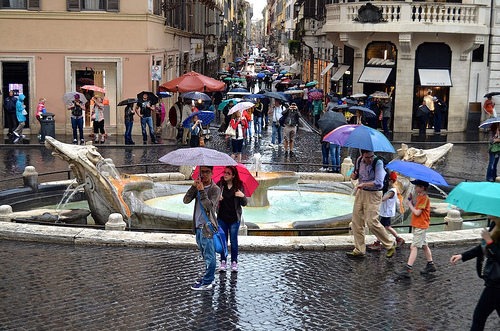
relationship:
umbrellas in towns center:
[4, 68, 499, 216] [1, 79, 497, 322]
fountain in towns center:
[2, 130, 499, 251] [1, 79, 497, 322]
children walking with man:
[319, 121, 449, 293] [322, 121, 401, 265]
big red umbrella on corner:
[155, 67, 229, 99] [1, 2, 214, 138]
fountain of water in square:
[2, 130, 499, 251] [1, 79, 497, 322]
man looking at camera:
[180, 163, 228, 293] [1, 79, 497, 322]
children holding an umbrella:
[392, 177, 437, 276] [381, 158, 454, 193]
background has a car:
[224, 3, 308, 168] [247, 55, 257, 65]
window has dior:
[73, 65, 107, 131] [82, 65, 104, 80]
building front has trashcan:
[1, 2, 214, 138] [37, 110, 61, 143]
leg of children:
[396, 233, 422, 281] [392, 177, 437, 276]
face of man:
[197, 163, 214, 186] [180, 163, 228, 293]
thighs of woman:
[215, 218, 242, 247] [215, 166, 248, 275]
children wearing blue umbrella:
[392, 177, 437, 276] [381, 158, 454, 193]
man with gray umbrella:
[180, 163, 228, 293] [158, 146, 239, 173]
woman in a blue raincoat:
[15, 91, 27, 138] [13, 93, 30, 123]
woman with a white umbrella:
[223, 100, 256, 161] [225, 101, 257, 118]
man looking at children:
[322, 121, 401, 265] [392, 177, 437, 276]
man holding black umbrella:
[134, 90, 161, 147] [136, 91, 161, 110]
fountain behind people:
[2, 130, 499, 251] [166, 145, 496, 330]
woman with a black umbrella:
[117, 96, 139, 146] [116, 99, 141, 109]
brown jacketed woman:
[215, 174, 248, 229] [215, 166, 248, 275]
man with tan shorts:
[281, 103, 303, 160] [280, 127, 299, 145]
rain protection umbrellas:
[1, 79, 497, 322] [4, 68, 499, 216]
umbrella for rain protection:
[318, 121, 398, 155] [322, 121, 401, 265]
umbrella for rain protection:
[158, 146, 239, 173] [160, 144, 238, 293]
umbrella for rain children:
[381, 158, 454, 193] [392, 177, 437, 276]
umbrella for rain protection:
[346, 106, 377, 120] [347, 105, 376, 130]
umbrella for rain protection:
[155, 67, 229, 99] [157, 70, 231, 136]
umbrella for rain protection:
[182, 107, 218, 132] [179, 110, 219, 147]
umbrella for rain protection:
[78, 84, 109, 96] [80, 84, 111, 144]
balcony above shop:
[323, 1, 484, 48] [307, 46, 482, 142]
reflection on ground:
[157, 242, 311, 330] [6, 226, 484, 322]